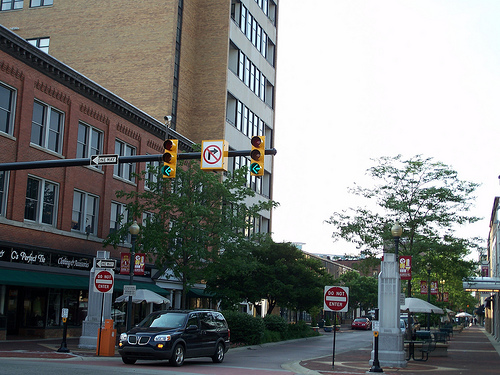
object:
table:
[401, 339, 429, 362]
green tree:
[318, 152, 486, 338]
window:
[113, 136, 123, 177]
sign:
[90, 155, 118, 166]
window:
[0, 82, 20, 139]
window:
[42, 177, 60, 228]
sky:
[276, 0, 499, 263]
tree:
[99, 142, 281, 310]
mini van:
[115, 307, 232, 368]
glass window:
[47, 108, 67, 155]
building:
[0, 22, 220, 342]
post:
[366, 331, 383, 372]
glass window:
[29, 98, 45, 148]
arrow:
[249, 161, 261, 175]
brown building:
[0, 0, 279, 339]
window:
[70, 188, 86, 232]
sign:
[395, 255, 413, 280]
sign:
[320, 283, 349, 313]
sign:
[91, 267, 113, 294]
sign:
[132, 252, 145, 277]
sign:
[117, 252, 133, 276]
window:
[23, 174, 42, 224]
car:
[351, 316, 372, 332]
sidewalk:
[298, 325, 498, 375]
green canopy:
[0, 267, 168, 295]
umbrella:
[112, 288, 174, 320]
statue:
[366, 251, 407, 369]